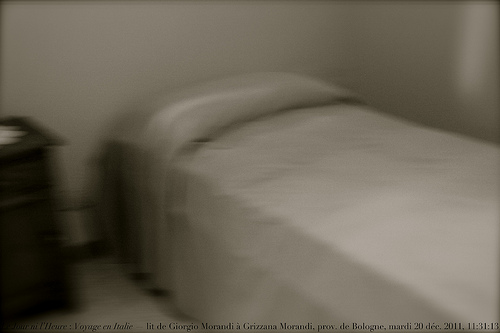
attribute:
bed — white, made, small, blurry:
[163, 93, 449, 222]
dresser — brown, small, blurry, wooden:
[4, 125, 70, 251]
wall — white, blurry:
[40, 34, 93, 63]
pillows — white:
[148, 70, 315, 107]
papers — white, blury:
[0, 118, 35, 142]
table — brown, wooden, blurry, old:
[0, 146, 53, 257]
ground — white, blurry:
[97, 281, 122, 311]